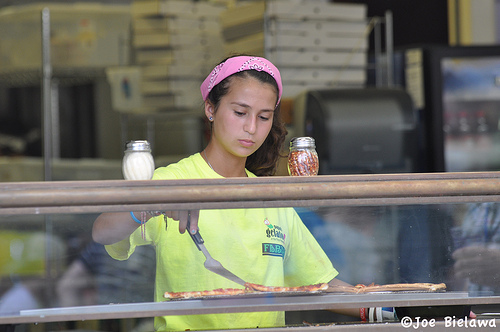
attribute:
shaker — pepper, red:
[286, 136, 322, 178]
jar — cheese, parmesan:
[121, 138, 155, 179]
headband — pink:
[197, 56, 283, 111]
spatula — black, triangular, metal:
[178, 219, 260, 290]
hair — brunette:
[203, 62, 289, 175]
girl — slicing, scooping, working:
[94, 56, 386, 331]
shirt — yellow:
[105, 152, 336, 323]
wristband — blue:
[361, 309, 384, 325]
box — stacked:
[240, 48, 368, 68]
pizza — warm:
[162, 281, 326, 301]